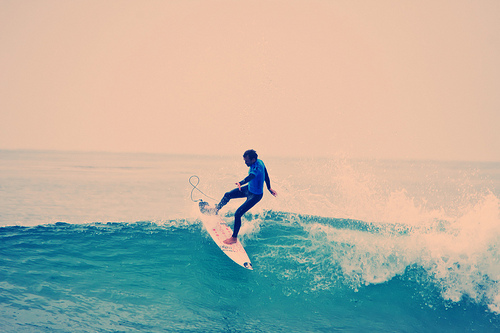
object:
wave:
[3, 212, 495, 329]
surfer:
[207, 148, 279, 245]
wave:
[318, 180, 447, 275]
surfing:
[159, 98, 499, 330]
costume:
[214, 160, 271, 240]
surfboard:
[193, 199, 255, 272]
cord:
[188, 173, 219, 202]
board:
[194, 199, 253, 270]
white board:
[200, 192, 256, 274]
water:
[0, 151, 498, 328]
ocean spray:
[52, 217, 359, 322]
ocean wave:
[4, 170, 476, 309]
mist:
[311, 176, 448, 241]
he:
[200, 147, 278, 244]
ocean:
[2, 210, 484, 322]